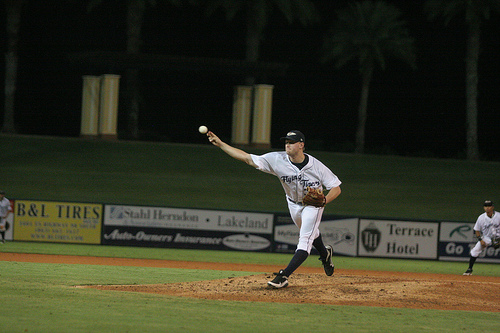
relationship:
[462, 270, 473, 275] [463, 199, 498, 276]
shoe of man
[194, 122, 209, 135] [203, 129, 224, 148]
ball in hand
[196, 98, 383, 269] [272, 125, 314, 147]
man has hat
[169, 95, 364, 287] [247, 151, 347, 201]
man has shirt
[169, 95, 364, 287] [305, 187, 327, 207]
man has glove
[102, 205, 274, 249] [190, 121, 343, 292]
sign behind man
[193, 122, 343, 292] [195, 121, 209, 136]
pitcher throwing baseball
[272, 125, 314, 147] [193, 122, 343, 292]
hat on pitcher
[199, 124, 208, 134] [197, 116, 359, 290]
baseball thrown by baseman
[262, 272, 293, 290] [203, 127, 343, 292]
cleat on player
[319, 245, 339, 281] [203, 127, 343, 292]
cleat on player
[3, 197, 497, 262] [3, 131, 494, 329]
wall at end of baseball field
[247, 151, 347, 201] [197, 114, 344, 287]
shirt on pitcher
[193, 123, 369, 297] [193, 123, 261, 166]
player delivering pitch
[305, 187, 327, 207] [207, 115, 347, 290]
glove worn by pitcher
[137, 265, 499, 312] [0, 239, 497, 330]
pitcher's mound on field